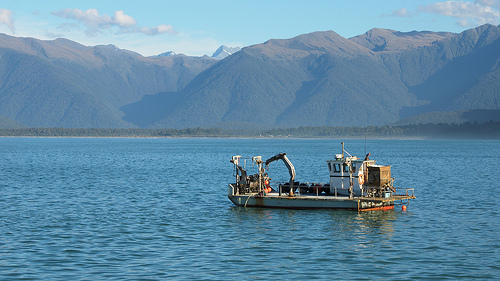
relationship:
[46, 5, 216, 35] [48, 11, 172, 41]
sky with clouds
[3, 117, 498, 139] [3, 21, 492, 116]
trees growing along base mountain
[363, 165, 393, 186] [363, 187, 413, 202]
brown box over platform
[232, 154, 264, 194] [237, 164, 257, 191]
poles with panels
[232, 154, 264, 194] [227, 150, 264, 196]
poles with rod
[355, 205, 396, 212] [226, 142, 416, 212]
stripe at rear boat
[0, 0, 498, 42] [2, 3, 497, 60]
cloud in sky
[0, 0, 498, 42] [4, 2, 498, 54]
cloud in sky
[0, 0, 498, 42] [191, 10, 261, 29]
cloud in sky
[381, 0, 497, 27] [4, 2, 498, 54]
cloud in sky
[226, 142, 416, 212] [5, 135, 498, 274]
boat in water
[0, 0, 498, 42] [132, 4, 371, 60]
cloud in sky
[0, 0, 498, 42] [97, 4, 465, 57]
cloud in sky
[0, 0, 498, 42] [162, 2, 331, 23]
cloud in sky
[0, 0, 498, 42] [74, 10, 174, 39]
cloud in sky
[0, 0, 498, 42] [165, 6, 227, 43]
cloud in sky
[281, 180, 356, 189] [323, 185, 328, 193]
railing in front objects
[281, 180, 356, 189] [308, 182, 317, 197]
railing in front objects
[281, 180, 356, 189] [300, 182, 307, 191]
railing in front objects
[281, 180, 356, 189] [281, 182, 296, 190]
railing in front objects